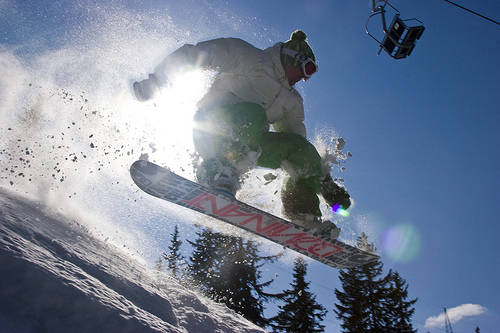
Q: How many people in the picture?
A: One.